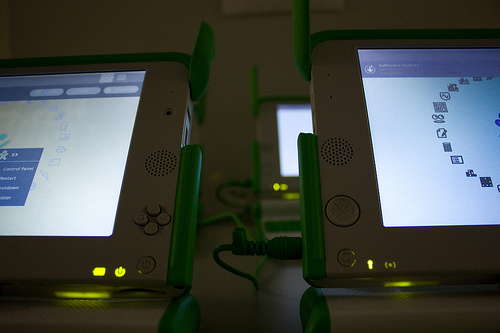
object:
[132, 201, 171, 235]
group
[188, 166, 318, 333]
table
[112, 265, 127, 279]
button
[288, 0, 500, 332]
computer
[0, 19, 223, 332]
computer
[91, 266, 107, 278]
green light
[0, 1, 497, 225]
wall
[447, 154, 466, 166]
images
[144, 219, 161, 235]
control buttons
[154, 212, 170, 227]
control buttons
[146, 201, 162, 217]
control buttons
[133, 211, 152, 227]
control buttons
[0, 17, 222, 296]
monitor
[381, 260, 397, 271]
button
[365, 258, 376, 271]
light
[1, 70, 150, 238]
screen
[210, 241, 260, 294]
cord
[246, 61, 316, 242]
electronic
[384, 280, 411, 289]
glow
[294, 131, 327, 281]
attachment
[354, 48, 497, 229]
systems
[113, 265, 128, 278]
power indicator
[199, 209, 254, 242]
wire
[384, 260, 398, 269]
power light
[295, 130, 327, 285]
side bar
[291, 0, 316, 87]
side bar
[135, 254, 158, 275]
power button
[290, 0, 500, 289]
computer monitor